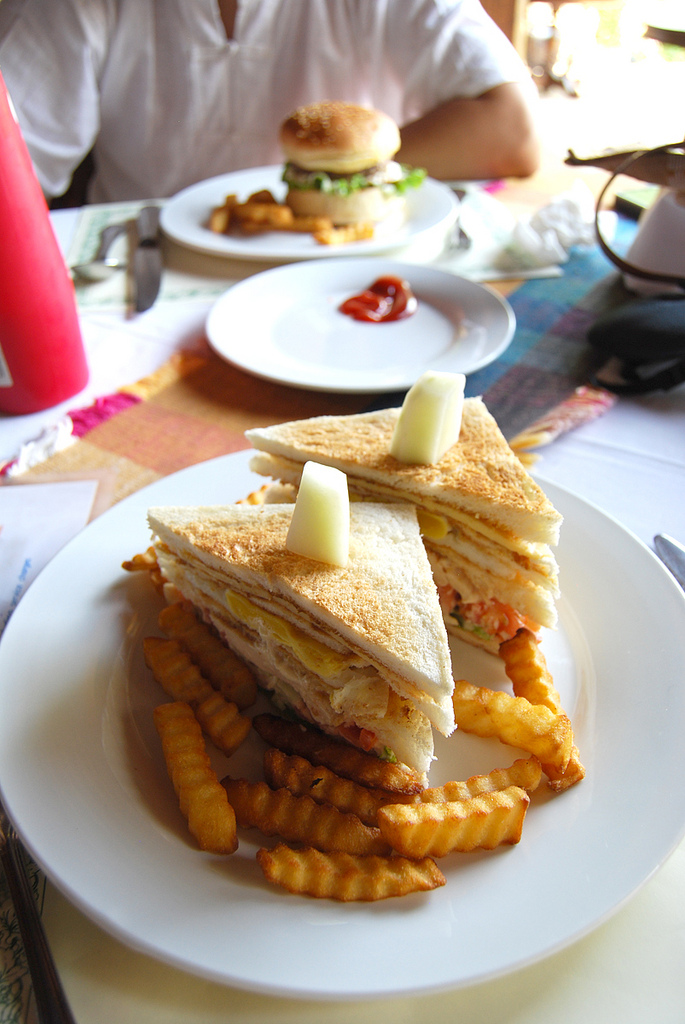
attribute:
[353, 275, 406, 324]
ketchup — red, dollop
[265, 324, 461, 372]
plate — round, white, triple decker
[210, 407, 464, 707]
sandwich — cut, toasted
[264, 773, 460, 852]
fries — crispy, crinkle cut, krinkle cut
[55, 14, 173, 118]
top — white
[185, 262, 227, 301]
place mat — plaid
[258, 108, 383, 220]
burger — small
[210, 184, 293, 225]
french fries — crinkle cut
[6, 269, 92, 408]
bottle — red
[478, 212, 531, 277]
napkin — crumpled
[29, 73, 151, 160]
shirt — white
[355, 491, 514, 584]
sandwiches — identical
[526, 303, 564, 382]
tablecloth — colorful